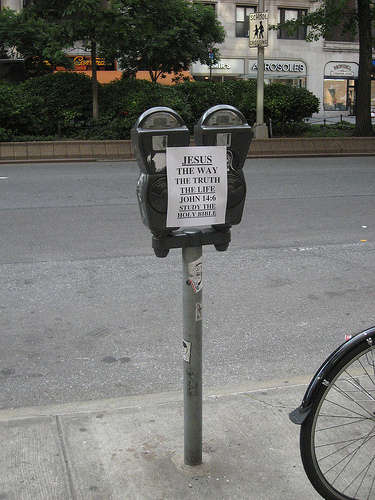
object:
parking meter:
[132, 101, 252, 462]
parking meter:
[130, 102, 196, 259]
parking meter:
[197, 102, 253, 253]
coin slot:
[153, 134, 170, 152]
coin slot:
[215, 132, 231, 150]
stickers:
[181, 255, 206, 371]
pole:
[182, 245, 204, 470]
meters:
[131, 106, 250, 259]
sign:
[164, 145, 229, 229]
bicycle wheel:
[289, 324, 374, 499]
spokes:
[316, 353, 374, 499]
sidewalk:
[0, 380, 374, 497]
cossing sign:
[248, 11, 271, 51]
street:
[0, 157, 372, 407]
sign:
[247, 8, 270, 48]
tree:
[0, 1, 221, 121]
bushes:
[0, 75, 323, 140]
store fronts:
[0, 1, 375, 116]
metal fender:
[286, 323, 373, 426]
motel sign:
[323, 59, 362, 80]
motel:
[305, 0, 371, 127]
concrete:
[0, 0, 375, 500]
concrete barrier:
[0, 138, 375, 161]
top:
[131, 103, 258, 141]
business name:
[65, 53, 120, 70]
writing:
[173, 156, 222, 218]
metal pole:
[255, 46, 270, 139]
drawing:
[254, 20, 267, 43]